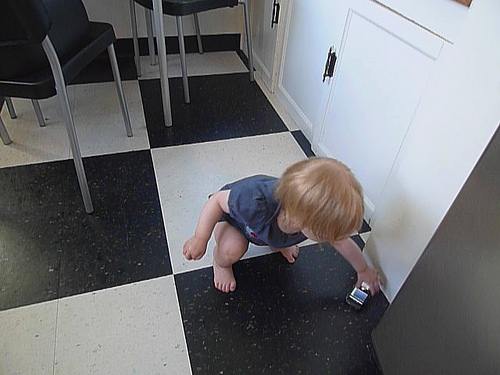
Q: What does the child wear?
A: Child wears blue clothes.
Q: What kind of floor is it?
A: Floor is made of black and white tiles.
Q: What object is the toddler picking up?
A: Toddler is picking up a cell phone.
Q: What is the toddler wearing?
A: Toddler is wearing a blue shirt.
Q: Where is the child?
A: On floor.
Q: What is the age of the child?
A: Toddler.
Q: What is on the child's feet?
A: No shoes.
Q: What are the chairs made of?
A: Plastic.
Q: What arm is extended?
A: Left.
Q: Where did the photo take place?
A: Kitchen.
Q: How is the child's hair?
A: Blonde.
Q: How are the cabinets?
A: White.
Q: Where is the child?
A: Kitchen.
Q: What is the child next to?
A: Fridge.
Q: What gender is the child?
A: Male.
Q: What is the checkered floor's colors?
A: Black and white.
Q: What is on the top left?
A: Chair.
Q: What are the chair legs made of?
A: Metal.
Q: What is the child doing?
A: Playing.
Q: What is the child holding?
A: Toy.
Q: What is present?
A: A baby.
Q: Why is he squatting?
A: To pick up the phone.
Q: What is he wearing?
A: Clothes.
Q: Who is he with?
A: Nobody.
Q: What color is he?
A: White.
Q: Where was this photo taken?
A: In a house.